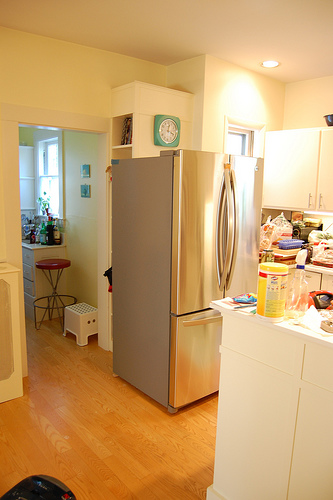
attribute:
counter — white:
[190, 296, 330, 498]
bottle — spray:
[283, 246, 312, 321]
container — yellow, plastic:
[249, 247, 291, 327]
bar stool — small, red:
[33, 257, 75, 329]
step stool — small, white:
[60, 300, 97, 346]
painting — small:
[78, 162, 92, 178]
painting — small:
[78, 183, 92, 200]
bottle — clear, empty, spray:
[266, 236, 331, 318]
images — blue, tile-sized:
[79, 162, 93, 199]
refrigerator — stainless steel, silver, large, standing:
[104, 142, 267, 414]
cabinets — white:
[255, 126, 331, 213]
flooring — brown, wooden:
[0, 309, 225, 498]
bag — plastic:
[259, 215, 291, 252]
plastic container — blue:
[277, 238, 303, 250]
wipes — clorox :
[257, 260, 289, 322]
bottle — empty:
[276, 241, 321, 328]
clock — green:
[158, 118, 177, 143]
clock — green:
[152, 113, 180, 147]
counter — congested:
[258, 255, 332, 278]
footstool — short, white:
[61, 301, 98, 345]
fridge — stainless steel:
[106, 141, 270, 416]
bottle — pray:
[286, 245, 308, 320]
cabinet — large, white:
[298, 138, 329, 182]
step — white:
[63, 301, 97, 345]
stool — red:
[26, 242, 90, 323]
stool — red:
[28, 258, 83, 327]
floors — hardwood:
[2, 324, 226, 496]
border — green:
[151, 114, 178, 147]